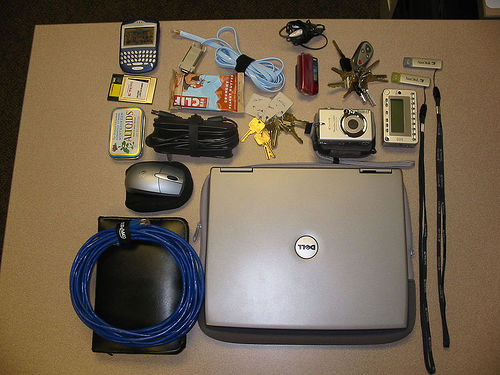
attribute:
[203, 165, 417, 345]
laptop — square, dell, gray, silver, closed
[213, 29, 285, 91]
wire-roll — blue, rolled-up, flat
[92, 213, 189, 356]
book — leather, black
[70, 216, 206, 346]
wire-roll — blue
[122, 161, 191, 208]
mouse — gray, small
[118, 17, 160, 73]
phone — analogue, wide, blackberry, blue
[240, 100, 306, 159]
keys — bundled, gold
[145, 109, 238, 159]
wires — black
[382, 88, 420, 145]
gadget — white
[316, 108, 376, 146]
camera — silver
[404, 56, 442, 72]
storage-device — silver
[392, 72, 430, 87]
storage-device — silver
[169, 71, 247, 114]
energy-bar — clif, clif brand